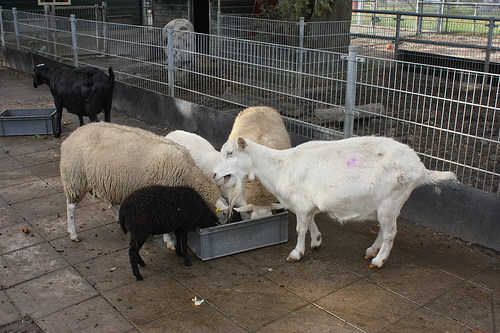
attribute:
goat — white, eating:
[213, 136, 459, 268]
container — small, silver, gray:
[185, 207, 289, 260]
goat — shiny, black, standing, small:
[31, 62, 116, 136]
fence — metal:
[1, 8, 499, 197]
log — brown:
[314, 102, 385, 125]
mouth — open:
[214, 171, 237, 189]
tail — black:
[107, 65, 115, 86]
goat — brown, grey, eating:
[60, 121, 234, 241]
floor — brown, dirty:
[1, 65, 499, 332]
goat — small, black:
[119, 185, 219, 280]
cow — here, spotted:
[161, 18, 196, 90]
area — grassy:
[351, 4, 499, 36]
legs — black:
[129, 233, 193, 282]